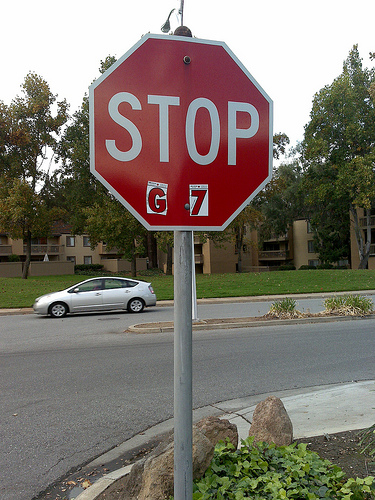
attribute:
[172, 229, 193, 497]
pole — gray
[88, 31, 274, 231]
sign — stop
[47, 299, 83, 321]
rims — silver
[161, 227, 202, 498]
pole — metal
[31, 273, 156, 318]
car — gray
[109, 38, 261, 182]
sign — STOP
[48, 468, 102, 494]
leaves — on the ground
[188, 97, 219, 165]
letter — O